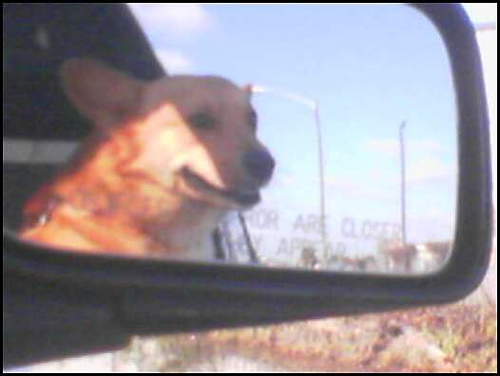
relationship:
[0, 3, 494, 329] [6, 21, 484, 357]
mirror on car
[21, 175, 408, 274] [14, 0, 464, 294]
printed mirror on mirror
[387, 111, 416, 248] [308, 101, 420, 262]
light on pole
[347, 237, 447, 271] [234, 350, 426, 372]
building on road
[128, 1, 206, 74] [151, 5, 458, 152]
cloud in sky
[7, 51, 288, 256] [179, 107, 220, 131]
dog has an eye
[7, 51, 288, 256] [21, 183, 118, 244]
dog has collar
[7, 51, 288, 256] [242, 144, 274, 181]
dog has nose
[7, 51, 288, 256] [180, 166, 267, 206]
dog has mouth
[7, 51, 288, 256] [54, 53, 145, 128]
dog has an ear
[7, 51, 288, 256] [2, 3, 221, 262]
dog out of window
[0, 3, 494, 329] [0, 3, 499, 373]
mirror on car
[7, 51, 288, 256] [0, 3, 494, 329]
dog reflected on mirror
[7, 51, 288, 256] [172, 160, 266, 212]
dog has dog's mouth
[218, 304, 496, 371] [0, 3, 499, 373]
dry grass next to car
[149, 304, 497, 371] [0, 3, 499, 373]
brown grass next to car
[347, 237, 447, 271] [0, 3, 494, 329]
building reflected on mirror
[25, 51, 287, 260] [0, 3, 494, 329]
dog in mirror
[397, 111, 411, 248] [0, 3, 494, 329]
light in mirror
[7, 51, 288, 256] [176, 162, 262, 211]
dog has mouth